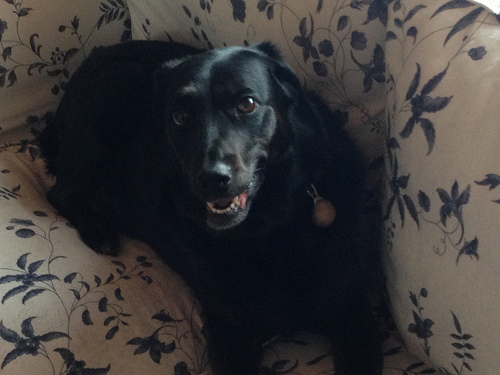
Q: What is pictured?
A: A black dog.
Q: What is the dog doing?
A: Sitting on the couch.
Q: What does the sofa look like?
A: Cream with blue flowers.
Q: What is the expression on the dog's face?
A: Smiling.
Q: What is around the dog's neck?
A: A collar.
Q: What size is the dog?
A: Large.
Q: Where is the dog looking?
A: At the camera.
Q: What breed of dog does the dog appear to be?
A: A labrador mix.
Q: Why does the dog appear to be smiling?
A: The dog's teeth are showing and the mouth is open.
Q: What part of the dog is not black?
A: The teeth and eyes.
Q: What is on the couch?
A: Black dog.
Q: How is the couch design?
A: Floral design.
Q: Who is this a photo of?
A: A dog.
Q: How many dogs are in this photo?
A: One.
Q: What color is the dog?
A: Black.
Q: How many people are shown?
A: None.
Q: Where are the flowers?
A: Under & around the dog.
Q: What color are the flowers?
A: Blue.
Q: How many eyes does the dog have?
A: Two.